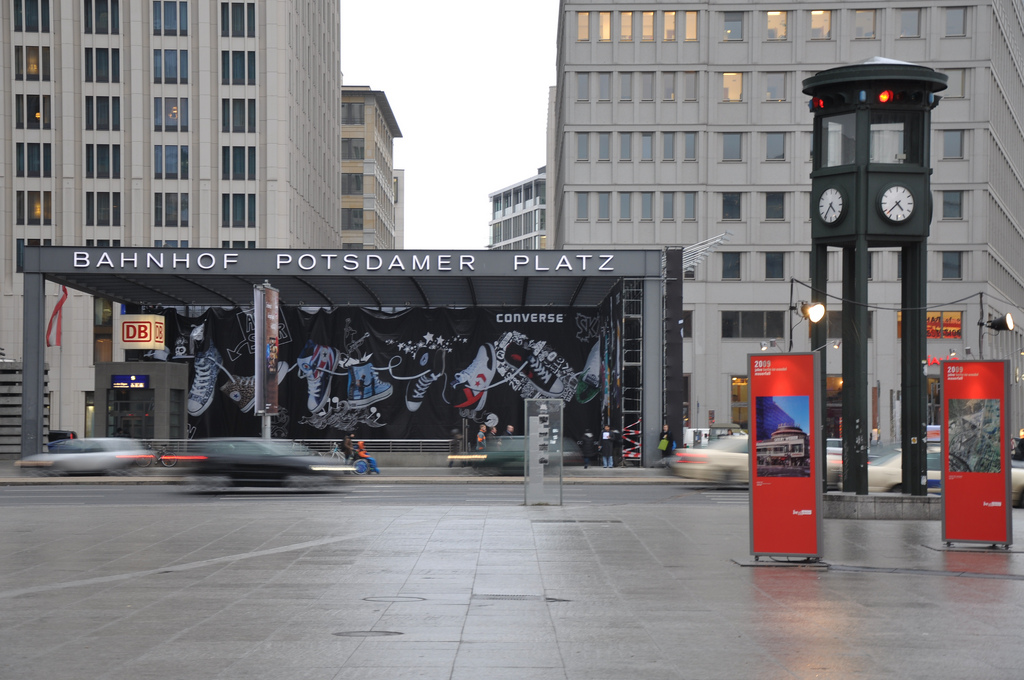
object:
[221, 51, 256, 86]
cabinet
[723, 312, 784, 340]
cabinet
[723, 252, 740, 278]
cabinet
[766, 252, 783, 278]
cabinet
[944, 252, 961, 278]
cabinet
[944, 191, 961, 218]
cabinet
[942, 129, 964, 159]
cabinet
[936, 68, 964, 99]
cabinet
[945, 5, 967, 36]
cabinet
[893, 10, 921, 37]
cabinet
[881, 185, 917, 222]
clock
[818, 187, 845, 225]
clock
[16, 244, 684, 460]
structure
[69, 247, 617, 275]
word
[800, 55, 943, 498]
monument